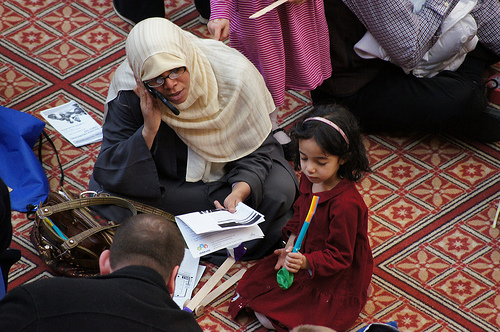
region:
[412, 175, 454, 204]
pattern on the carpet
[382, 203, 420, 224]
pattern on the carpet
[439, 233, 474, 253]
pattern on the carpet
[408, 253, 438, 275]
pattern on the carpet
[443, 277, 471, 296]
pattern on the carpet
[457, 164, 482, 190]
pattern on the carpet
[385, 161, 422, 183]
pattern on the carpet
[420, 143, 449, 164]
pattern on the carpet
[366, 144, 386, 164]
pattern on the carpet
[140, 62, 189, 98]
pair of glasses on a face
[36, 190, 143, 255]
brown handle of a purse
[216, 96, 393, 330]
child with black hair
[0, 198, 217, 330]
person wearing black shirt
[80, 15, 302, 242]
woman talking on the phone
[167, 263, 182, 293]
ear of a person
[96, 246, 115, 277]
ear of a person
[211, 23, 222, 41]
finger of a person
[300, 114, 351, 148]
pink head band on a child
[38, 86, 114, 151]
piece of paper on the ground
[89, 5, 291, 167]
Woman on cellphone wearing a burka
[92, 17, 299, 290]
Woman wearing a burka sitting on a rug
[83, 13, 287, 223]
Woman wearing glasses and a burka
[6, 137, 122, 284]
Purse on a rug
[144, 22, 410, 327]
Little girl sitting on a rug next to a woman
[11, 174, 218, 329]
Man wearing a black jacket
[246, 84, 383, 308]
Little girl holding a toy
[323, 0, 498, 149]
Lower part of a man sitting on a rug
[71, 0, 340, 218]
Woman wearing a beige burka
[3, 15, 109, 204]
Brochure and bag on a rug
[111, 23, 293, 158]
Woman wearing cloth on head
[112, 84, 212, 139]
Woman talking on the phone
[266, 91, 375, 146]
Girl wearing a headband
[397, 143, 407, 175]
The floor has a distinct pattern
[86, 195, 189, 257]
Man is starting to go bald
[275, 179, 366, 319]
Girl is wearing a red dress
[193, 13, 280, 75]
Woman touching her shoulder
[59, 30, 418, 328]
Family sitting on the floor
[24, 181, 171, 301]
Purse sitting on floor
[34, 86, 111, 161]
Brochure on the floor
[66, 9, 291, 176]
woman wearing white hijab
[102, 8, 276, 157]
hijab has line indentations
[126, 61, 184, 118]
woman holding phone on ear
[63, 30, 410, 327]
woman and child sitting on floor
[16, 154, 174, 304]
purse sitting next to woman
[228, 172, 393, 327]
girl wearing dark red dress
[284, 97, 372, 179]
girl has black hairl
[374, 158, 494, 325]
carpet is floral pattern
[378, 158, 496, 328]
carpet is red and beige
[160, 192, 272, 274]
woman holding folded paper